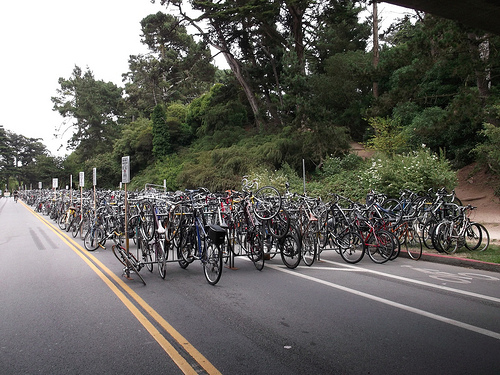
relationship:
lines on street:
[234, 235, 498, 339] [0, 186, 499, 372]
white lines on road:
[327, 261, 468, 306] [302, 292, 417, 353]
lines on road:
[116, 285, 218, 373] [18, 282, 383, 349]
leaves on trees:
[393, 59, 433, 101] [344, 7, 490, 167]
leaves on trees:
[317, 35, 342, 85] [190, 0, 478, 186]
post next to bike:
[121, 182, 130, 276] [173, 204, 229, 284]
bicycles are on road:
[18, 176, 486, 281] [126, 259, 498, 353]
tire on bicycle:
[457, 216, 499, 282] [429, 205, 486, 267]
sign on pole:
[120, 155, 131, 183] [123, 182, 128, 275]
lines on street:
[14, 193, 239, 370] [0, 186, 499, 372]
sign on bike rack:
[120, 155, 130, 283] [123, 205, 403, 272]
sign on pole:
[89, 165, 99, 186] [93, 166, 101, 206]